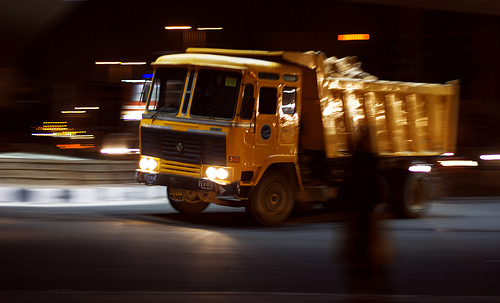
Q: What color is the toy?
A: Yellow.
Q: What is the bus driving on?
A: The road.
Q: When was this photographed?
A: Night time.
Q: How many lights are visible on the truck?
A: Two.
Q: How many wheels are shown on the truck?
A: Three.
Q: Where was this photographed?
A: On a street.